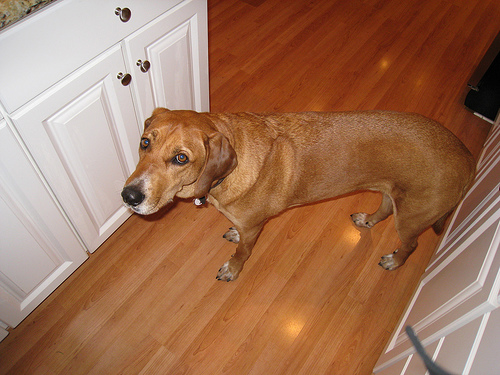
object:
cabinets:
[0, 119, 89, 371]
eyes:
[172, 151, 197, 166]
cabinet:
[367, 114, 498, 193]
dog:
[121, 105, 477, 284]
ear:
[190, 131, 237, 198]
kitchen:
[0, 5, 497, 373]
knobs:
[111, 7, 151, 88]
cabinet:
[2, 0, 210, 253]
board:
[0, 0, 499, 373]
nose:
[119, 181, 144, 205]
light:
[280, 310, 311, 349]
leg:
[212, 215, 264, 283]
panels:
[0, 119, 89, 330]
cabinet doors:
[7, 1, 210, 257]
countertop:
[3, 1, 18, 15]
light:
[336, 229, 356, 246]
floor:
[0, 0, 499, 374]